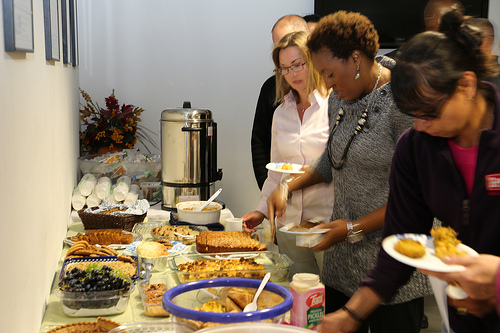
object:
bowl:
[162, 276, 294, 332]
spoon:
[241, 270, 271, 314]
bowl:
[52, 277, 136, 317]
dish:
[176, 200, 224, 224]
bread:
[93, 231, 99, 241]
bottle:
[289, 272, 327, 332]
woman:
[269, 8, 438, 332]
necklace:
[326, 61, 382, 170]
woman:
[240, 31, 340, 281]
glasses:
[277, 60, 308, 75]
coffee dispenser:
[157, 99, 225, 211]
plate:
[278, 221, 333, 235]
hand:
[311, 219, 353, 253]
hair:
[271, 29, 329, 103]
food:
[175, 256, 274, 282]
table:
[44, 161, 321, 333]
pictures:
[1, 0, 35, 55]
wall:
[0, 1, 84, 332]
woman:
[317, 9, 500, 332]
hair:
[389, 5, 489, 122]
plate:
[265, 161, 306, 174]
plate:
[379, 231, 481, 274]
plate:
[59, 243, 122, 262]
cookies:
[74, 249, 92, 254]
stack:
[77, 174, 97, 197]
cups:
[70, 194, 87, 211]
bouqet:
[72, 83, 160, 160]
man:
[248, 13, 313, 191]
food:
[392, 237, 427, 259]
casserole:
[184, 203, 219, 211]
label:
[303, 292, 325, 331]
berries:
[96, 280, 104, 286]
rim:
[162, 276, 295, 323]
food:
[299, 217, 325, 229]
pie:
[43, 313, 117, 332]